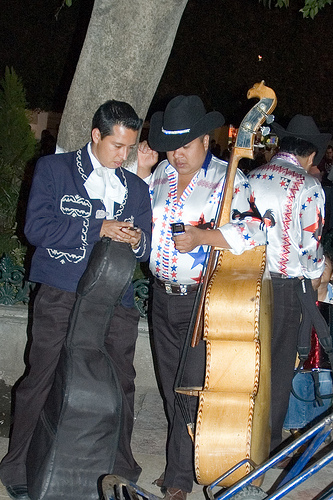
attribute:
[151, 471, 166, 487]
shoe — brown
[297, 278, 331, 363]
strap —  long , black 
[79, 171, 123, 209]
tie — White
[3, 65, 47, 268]
tree — tall, green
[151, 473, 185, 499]
shoe — brown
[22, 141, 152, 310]
shirt — blue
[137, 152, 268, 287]
shirt — white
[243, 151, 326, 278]
shirt — white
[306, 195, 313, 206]
star — red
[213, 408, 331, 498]
pole — blue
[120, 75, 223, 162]
hat — cowboy, black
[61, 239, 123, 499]
case — cello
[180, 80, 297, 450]
instrument — brown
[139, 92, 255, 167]
hat — black 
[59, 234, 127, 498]
case — black